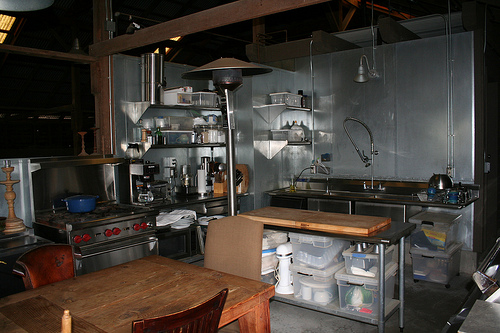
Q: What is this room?
A: Kitchen.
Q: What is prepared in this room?
A: Food.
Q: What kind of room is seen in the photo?
A: Kitchen.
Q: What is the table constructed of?
A: Wood.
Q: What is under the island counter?
A: Plastic containers.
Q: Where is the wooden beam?
A: Near the ceiling.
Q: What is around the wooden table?
A: Chairs.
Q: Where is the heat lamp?
A: Beside the counter.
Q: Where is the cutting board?
A: On the island.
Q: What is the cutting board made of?
A: Wood.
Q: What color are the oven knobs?
A: Red.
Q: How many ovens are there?
A: One.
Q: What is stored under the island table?
A: Cooking supplies.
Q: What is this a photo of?
A: A kitchen.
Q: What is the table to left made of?
A: Wood.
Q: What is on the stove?
A: A pot.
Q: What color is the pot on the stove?
A: Blue.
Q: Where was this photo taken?
A: In a commercial kitchen.